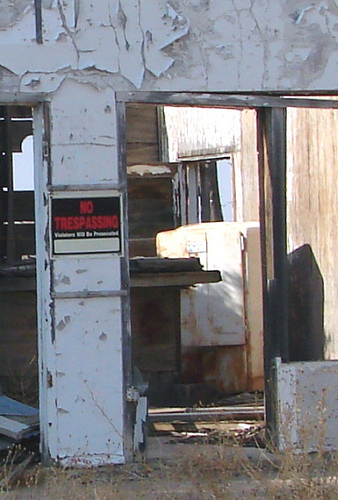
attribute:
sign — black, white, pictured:
[48, 187, 121, 257]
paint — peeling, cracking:
[1, 1, 337, 465]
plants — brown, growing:
[1, 386, 336, 499]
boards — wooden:
[1, 100, 335, 358]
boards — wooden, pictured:
[145, 395, 268, 447]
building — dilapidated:
[0, 1, 335, 466]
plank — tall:
[5, 259, 202, 272]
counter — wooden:
[2, 257, 225, 397]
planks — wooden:
[3, 188, 34, 262]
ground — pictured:
[0, 397, 335, 499]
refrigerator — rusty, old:
[155, 221, 268, 394]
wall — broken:
[49, 92, 124, 468]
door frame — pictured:
[110, 86, 279, 464]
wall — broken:
[1, 2, 336, 94]